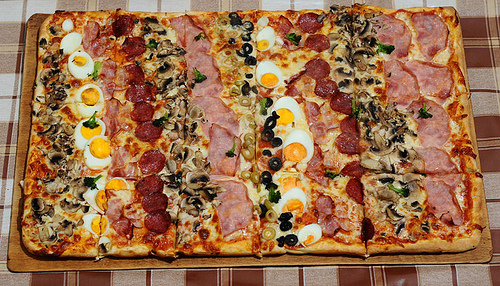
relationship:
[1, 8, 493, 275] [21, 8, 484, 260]
board holding pizza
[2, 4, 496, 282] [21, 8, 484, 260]
tablecloth holding pizza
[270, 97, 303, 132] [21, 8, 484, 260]
egg sitting on pizza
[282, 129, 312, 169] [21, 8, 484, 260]
egg sitting on pizza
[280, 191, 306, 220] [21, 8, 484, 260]
egg sitting on pizza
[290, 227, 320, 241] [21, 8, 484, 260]
egg sitting on pizza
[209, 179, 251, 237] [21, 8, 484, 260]
ham sliced on pizza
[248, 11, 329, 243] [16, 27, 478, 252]
egg slices on pizza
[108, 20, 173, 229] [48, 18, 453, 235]
meats on pizza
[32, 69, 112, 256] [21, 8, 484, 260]
mushrooms on pizza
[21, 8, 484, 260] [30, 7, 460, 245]
pizza covered in toppings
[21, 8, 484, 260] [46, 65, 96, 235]
pizza with mushroom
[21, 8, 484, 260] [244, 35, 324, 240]
pizza with eggs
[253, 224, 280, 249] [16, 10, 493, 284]
olive on pizza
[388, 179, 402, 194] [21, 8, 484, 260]
broccoli on pizza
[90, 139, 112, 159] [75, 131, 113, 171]
yolk of an egg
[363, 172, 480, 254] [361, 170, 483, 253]
crust of a slice